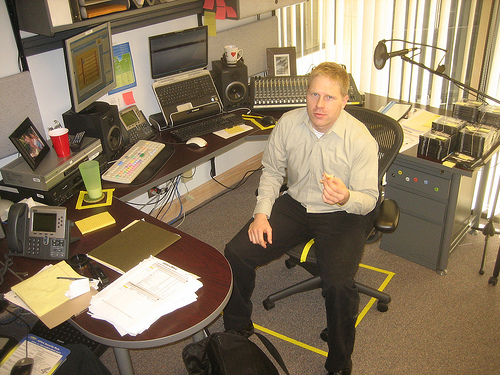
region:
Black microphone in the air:
[352, 27, 496, 118]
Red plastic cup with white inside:
[44, 120, 76, 160]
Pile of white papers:
[89, 251, 201, 341]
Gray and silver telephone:
[9, 191, 74, 268]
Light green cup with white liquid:
[71, 152, 109, 207]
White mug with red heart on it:
[221, 42, 245, 66]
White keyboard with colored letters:
[100, 141, 174, 190]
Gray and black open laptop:
[135, 30, 225, 123]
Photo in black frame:
[5, 119, 50, 171]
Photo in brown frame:
[265, 42, 300, 85]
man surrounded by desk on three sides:
[83, 40, 463, 341]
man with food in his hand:
[245, 47, 395, 272]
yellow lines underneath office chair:
[261, 57, 421, 353]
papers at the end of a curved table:
[85, 236, 240, 348]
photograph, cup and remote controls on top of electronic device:
[5, 102, 100, 199]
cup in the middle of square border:
[61, 140, 131, 215]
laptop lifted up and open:
[140, 20, 240, 135]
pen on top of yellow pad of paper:
[25, 256, 86, 321]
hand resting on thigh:
[220, 165, 295, 260]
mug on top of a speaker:
[208, 31, 256, 116]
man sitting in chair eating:
[223, 61, 399, 374]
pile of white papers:
[86, 253, 208, 336]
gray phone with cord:
[3, 199, 72, 268]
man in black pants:
[218, 59, 378, 373]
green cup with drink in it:
[72, 158, 112, 203]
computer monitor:
[56, 15, 124, 117]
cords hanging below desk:
[116, 158, 264, 230]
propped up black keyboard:
[145, 68, 235, 120]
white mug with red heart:
[222, 43, 245, 67]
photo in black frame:
[5, 114, 53, 170]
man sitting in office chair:
[218, 60, 406, 372]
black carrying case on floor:
[183, 327, 298, 373]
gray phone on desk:
[8, 200, 70, 261]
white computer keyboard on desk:
[103, 137, 162, 186]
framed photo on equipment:
[8, 116, 50, 171]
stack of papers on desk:
[86, 252, 206, 337]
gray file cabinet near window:
[385, 154, 485, 271]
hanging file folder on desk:
[87, 215, 179, 278]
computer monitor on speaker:
[63, 17, 117, 109]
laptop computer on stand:
[148, 24, 224, 131]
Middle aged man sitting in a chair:
[239, 55, 393, 367]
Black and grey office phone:
[4, 193, 89, 265]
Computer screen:
[54, 28, 140, 110]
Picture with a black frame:
[4, 110, 59, 174]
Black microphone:
[371, 28, 498, 107]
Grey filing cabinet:
[385, 142, 480, 294]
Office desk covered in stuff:
[0, 85, 255, 343]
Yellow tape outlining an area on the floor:
[246, 259, 493, 346]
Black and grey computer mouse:
[1, 346, 43, 373]